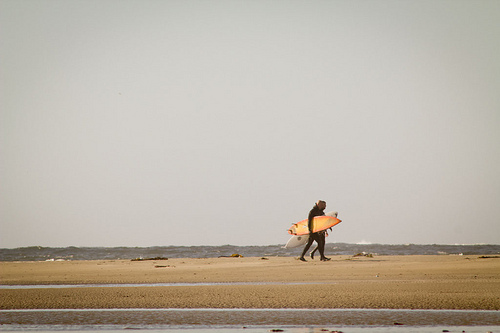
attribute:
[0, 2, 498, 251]
clouds — white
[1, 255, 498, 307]
sand — brown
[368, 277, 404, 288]
sand — brown 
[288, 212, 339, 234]
surfboard — orange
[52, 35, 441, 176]
sky — BIG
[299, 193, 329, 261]
man — walking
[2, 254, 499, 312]
ground — sandy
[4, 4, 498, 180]
sky — GREY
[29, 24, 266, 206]
sky — CLEAR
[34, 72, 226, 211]
sky — overcast